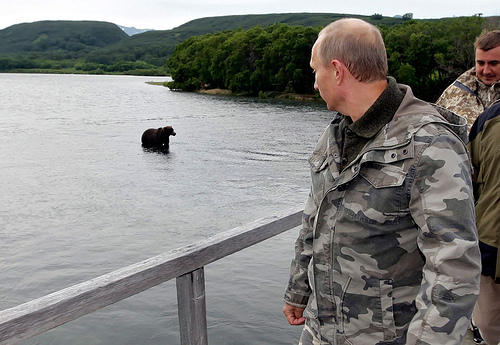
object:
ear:
[331, 59, 344, 86]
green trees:
[0, 12, 500, 100]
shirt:
[339, 75, 405, 172]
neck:
[336, 74, 389, 122]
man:
[437, 28, 500, 131]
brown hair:
[473, 29, 500, 52]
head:
[163, 126, 176, 137]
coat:
[435, 66, 500, 134]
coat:
[282, 83, 483, 345]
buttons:
[332, 148, 408, 172]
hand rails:
[0, 201, 317, 345]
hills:
[0, 11, 500, 91]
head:
[307, 17, 390, 111]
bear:
[142, 126, 177, 155]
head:
[472, 31, 499, 85]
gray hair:
[316, 18, 389, 84]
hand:
[282, 299, 306, 326]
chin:
[327, 100, 343, 111]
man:
[280, 18, 479, 345]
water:
[1, 71, 440, 345]